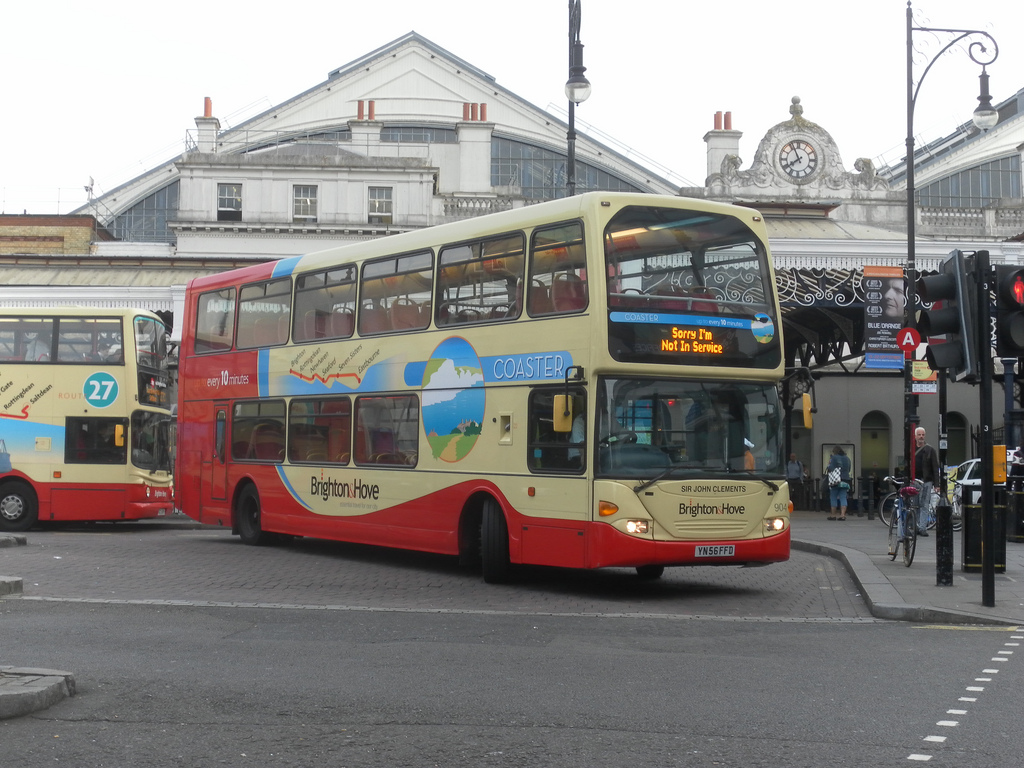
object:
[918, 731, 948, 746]
lines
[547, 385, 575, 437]
mirror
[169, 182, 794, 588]
bus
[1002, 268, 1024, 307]
light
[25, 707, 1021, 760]
crack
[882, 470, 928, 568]
bicycle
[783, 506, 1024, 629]
sidewalk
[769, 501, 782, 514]
number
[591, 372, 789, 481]
windshield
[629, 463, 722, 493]
wiper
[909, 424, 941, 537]
guy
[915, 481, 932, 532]
jeans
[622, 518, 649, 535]
headlight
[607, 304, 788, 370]
display module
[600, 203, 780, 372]
windshield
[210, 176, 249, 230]
window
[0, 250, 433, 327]
building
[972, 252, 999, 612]
pole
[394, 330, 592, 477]
advertisement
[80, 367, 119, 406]
27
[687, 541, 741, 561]
plate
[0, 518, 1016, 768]
roadway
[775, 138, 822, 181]
clock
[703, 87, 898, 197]
tower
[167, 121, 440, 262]
building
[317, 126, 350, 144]
window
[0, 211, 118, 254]
building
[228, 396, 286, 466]
window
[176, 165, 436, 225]
wall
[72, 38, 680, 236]
wall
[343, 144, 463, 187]
wall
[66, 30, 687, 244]
building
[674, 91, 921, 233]
building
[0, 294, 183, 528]
buses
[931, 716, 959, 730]
lines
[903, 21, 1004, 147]
street light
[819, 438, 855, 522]
person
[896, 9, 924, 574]
pole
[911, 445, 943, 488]
jacket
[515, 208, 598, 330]
window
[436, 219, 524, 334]
window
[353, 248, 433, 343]
window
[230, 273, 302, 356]
window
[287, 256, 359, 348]
window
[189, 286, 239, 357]
window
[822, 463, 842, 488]
bag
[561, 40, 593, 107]
light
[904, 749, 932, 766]
line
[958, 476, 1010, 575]
can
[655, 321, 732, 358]
sign